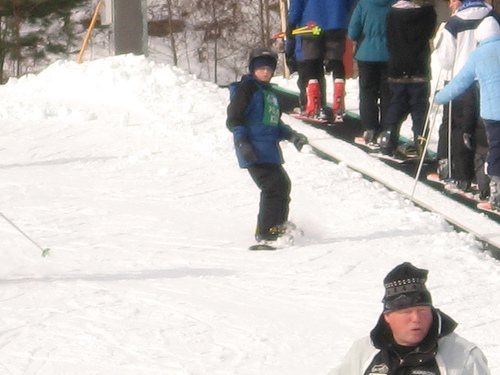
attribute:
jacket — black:
[321, 333, 489, 374]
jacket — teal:
[224, 74, 287, 166]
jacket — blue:
[345, 3, 392, 62]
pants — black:
[353, 62, 388, 151]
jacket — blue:
[228, 77, 310, 166]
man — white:
[327, 259, 487, 373]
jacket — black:
[385, 6, 436, 78]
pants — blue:
[380, 76, 430, 148]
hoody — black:
[365, 2, 445, 94]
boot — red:
[301, 80, 321, 115]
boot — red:
[331, 82, 345, 112]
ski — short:
[290, 111, 327, 123]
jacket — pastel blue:
[429, 37, 497, 124]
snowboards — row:
[234, 208, 321, 285]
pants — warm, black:
[246, 164, 290, 241]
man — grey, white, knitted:
[340, 249, 466, 364]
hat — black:
[383, 261, 441, 304]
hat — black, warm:
[357, 221, 454, 336]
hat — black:
[374, 257, 438, 310]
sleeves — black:
[225, 72, 285, 137]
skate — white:
[255, 229, 293, 246]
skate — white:
[278, 225, 305, 241]